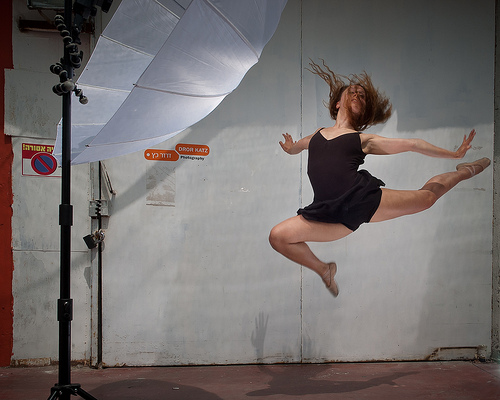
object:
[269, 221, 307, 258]
knee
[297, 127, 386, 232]
black outfit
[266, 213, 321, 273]
right leg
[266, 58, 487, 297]
light skinned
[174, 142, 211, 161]
signs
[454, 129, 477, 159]
hand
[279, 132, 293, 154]
hand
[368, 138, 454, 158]
arms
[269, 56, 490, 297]
woman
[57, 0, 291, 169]
umbrella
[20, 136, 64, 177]
sign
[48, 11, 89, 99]
electric wires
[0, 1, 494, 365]
wall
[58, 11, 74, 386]
pole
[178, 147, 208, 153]
hebrew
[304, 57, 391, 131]
brown hair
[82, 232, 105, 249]
padlock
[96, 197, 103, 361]
pole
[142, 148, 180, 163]
signs